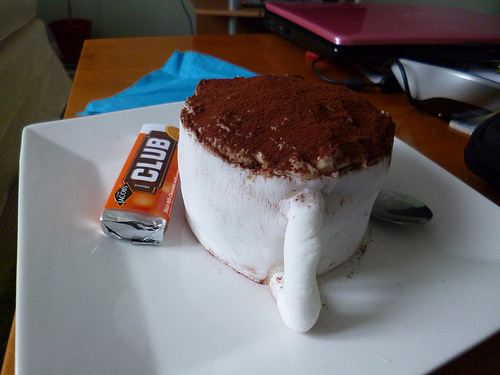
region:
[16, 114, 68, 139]
Edge of a white plate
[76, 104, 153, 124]
Edge of a white plate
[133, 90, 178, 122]
Edge of a white plate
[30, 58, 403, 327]
Food sitting on the plate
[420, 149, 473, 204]
Edge of a white plate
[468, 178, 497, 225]
Edge of a white plate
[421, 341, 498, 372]
Edge of a white plate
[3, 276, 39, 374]
Edge of a white plate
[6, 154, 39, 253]
Edge of a white plate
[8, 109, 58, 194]
Edge of a white plate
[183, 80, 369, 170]
chocolate topping on dessert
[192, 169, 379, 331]
cup made out of marshmellow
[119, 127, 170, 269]
name of product on the front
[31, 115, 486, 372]
dessert on a white plate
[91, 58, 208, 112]
blue napkin on the side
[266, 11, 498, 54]
pink top of computer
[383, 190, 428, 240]
spoon behind the cup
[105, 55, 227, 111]
napkin next to dish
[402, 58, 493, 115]
silver device on its side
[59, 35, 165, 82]
table is made of wood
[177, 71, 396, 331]
A cake in the shape of a cup.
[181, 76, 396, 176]
Chocolate powder topping on the icing.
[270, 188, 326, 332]
The handle of the cup-shaped cake.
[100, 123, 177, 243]
Candy bar chocolate brand 'CLUB'.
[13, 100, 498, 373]
A ceramic white tray holding the cake.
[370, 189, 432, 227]
Part of the spoon visible.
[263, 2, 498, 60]
Purple colored closed laptop.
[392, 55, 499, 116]
Mouse lying in inverted position.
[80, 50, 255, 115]
Blue napkin beside the tray.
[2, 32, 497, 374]
Brown table on which cake and laptop are kept.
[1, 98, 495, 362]
Square white plate on table.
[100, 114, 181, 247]
Piece of candy in wrapper.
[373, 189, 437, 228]
Silver spoon on white plate.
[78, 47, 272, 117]
Blue napkin laying on table.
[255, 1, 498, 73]
Pink laptop sitting on table.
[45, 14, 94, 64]
Dark flower pot in corner.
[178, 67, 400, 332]
White coffee mug on plate.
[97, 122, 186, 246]
Candy in orange and brown wrapper.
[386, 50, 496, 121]
Silver and black mouse.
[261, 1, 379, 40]
Shadow on top of laptop.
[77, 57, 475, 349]
Cup of cappuccino.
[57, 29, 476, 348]
A very messy treat.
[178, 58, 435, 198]
Overflowing cinnamon.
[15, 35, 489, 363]
A messy treat.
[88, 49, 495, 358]
The cup of cinnamon.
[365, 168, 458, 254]
A silver spoon for eating.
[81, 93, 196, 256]
Orange flavored club chocolate bar.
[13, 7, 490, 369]
Having a treat alone.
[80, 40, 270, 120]
Blue napkin defintley in need.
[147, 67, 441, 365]
A marsh mellow cup.